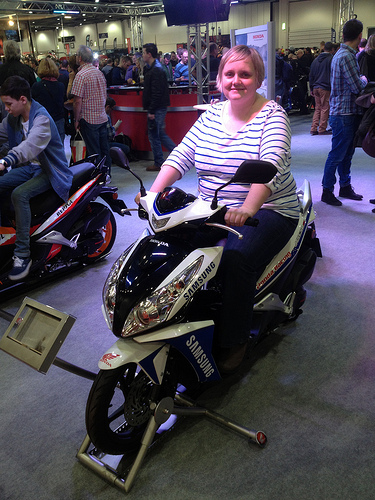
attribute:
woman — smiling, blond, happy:
[133, 44, 301, 371]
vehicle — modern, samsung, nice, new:
[83, 146, 323, 457]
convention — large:
[1, 2, 374, 500]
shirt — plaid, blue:
[329, 44, 367, 117]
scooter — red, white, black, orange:
[2, 152, 118, 303]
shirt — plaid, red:
[69, 61, 111, 124]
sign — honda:
[229, 22, 274, 105]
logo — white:
[185, 336, 216, 379]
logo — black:
[183, 261, 217, 301]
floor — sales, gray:
[0, 112, 373, 498]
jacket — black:
[143, 59, 170, 110]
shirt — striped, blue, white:
[160, 97, 301, 220]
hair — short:
[215, 45, 266, 96]